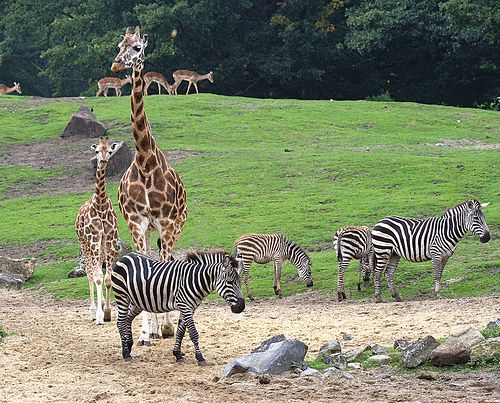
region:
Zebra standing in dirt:
[107, 247, 249, 364]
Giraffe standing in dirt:
[62, 137, 132, 327]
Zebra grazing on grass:
[229, 223, 323, 304]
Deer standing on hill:
[169, 67, 214, 99]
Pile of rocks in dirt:
[222, 321, 498, 383]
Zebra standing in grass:
[368, 200, 497, 300]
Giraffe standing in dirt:
[107, 29, 189, 349]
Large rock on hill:
[56, 102, 116, 142]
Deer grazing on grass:
[139, 69, 177, 99]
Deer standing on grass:
[93, 74, 133, 102]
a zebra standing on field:
[370, 197, 492, 302]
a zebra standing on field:
[330, 223, 377, 299]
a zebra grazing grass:
[231, 230, 316, 301]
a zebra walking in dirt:
[107, 250, 248, 365]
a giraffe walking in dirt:
[110, 25, 189, 345]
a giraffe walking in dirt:
[73, 136, 120, 323]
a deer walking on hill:
[169, 68, 215, 93]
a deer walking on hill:
[95, 74, 132, 99]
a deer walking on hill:
[0, 80, 25, 93]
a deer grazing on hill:
[142, 68, 173, 93]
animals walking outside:
[2, 30, 494, 362]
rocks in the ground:
[238, 323, 498, 369]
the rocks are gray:
[225, 328, 495, 383]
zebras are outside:
[112, 213, 495, 357]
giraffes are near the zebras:
[61, 37, 198, 326]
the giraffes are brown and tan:
[72, 33, 191, 308]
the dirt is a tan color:
[19, 308, 491, 398]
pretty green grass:
[19, 93, 492, 298]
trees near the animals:
[11, 3, 491, 86]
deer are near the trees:
[6, 66, 218, 91]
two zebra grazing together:
[215, 216, 374, 308]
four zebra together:
[71, 194, 498, 369]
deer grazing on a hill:
[8, 61, 233, 98]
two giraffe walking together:
[34, 21, 191, 332]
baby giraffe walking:
[34, 118, 131, 326]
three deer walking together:
[87, 62, 228, 99]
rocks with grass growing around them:
[240, 321, 499, 378]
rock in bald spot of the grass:
[51, 138, 199, 205]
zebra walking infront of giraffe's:
[94, 236, 249, 357]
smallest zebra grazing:
[234, 226, 319, 298]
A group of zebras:
[112, 202, 495, 364]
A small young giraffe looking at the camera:
[77, 137, 130, 319]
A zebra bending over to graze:
[232, 232, 314, 299]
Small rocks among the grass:
[230, 330, 499, 375]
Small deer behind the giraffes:
[88, 72, 221, 94]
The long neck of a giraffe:
[106, 34, 168, 157]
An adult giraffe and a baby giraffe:
[68, 31, 196, 323]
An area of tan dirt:
[3, 298, 497, 399]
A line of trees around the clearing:
[0, 0, 487, 109]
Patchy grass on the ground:
[2, 93, 496, 295]